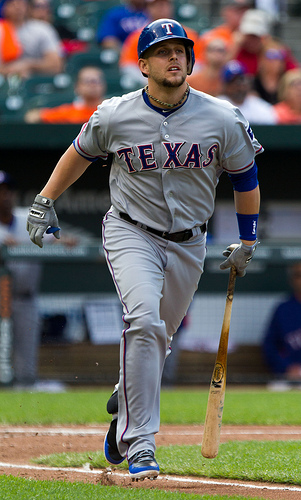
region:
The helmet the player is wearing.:
[137, 20, 197, 72]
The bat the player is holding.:
[205, 244, 236, 463]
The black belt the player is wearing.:
[117, 213, 207, 242]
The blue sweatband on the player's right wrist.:
[233, 210, 258, 237]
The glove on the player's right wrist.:
[219, 244, 256, 277]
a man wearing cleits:
[113, 428, 176, 496]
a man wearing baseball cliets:
[91, 411, 174, 490]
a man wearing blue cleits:
[103, 411, 188, 499]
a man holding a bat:
[196, 229, 267, 474]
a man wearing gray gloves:
[231, 234, 260, 292]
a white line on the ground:
[22, 447, 155, 493]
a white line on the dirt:
[29, 448, 157, 496]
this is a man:
[24, 17, 264, 478]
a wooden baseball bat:
[200, 233, 250, 476]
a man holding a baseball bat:
[10, 13, 269, 470]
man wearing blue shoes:
[74, 402, 179, 488]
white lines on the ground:
[10, 402, 299, 497]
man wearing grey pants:
[64, 197, 226, 458]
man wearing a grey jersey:
[62, 88, 271, 252]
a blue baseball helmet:
[121, 9, 204, 76]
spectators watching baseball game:
[4, 2, 290, 182]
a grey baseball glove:
[16, 183, 70, 262]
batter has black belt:
[114, 199, 202, 250]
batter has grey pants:
[85, 228, 207, 450]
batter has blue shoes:
[101, 410, 164, 482]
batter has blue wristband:
[234, 195, 258, 249]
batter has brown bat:
[155, 258, 250, 470]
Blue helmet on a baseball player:
[129, 19, 194, 75]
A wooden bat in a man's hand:
[201, 268, 237, 458]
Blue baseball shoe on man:
[128, 454, 158, 477]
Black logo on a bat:
[212, 362, 223, 388]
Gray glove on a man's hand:
[22, 194, 61, 244]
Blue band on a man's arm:
[233, 209, 259, 244]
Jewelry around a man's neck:
[141, 84, 190, 108]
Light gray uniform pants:
[98, 207, 210, 454]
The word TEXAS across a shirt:
[114, 136, 218, 171]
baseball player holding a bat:
[21, 7, 268, 482]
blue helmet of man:
[129, 16, 193, 49]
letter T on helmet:
[158, 15, 173, 30]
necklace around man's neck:
[134, 78, 189, 101]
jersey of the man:
[60, 83, 255, 227]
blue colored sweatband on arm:
[230, 209, 254, 237]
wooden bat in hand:
[189, 260, 239, 456]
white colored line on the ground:
[1, 455, 296, 490]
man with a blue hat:
[211, 59, 273, 121]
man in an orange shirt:
[26, 67, 113, 126]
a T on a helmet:
[159, 22, 171, 37]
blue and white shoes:
[125, 451, 158, 480]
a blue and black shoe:
[106, 417, 124, 467]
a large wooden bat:
[202, 262, 239, 459]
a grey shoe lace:
[137, 447, 151, 463]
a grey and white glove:
[24, 196, 61, 248]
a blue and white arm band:
[234, 210, 261, 242]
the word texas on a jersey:
[114, 141, 215, 175]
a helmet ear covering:
[185, 48, 196, 75]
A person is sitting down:
[115, 6, 204, 95]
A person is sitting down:
[177, 32, 217, 96]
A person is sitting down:
[201, 58, 262, 140]